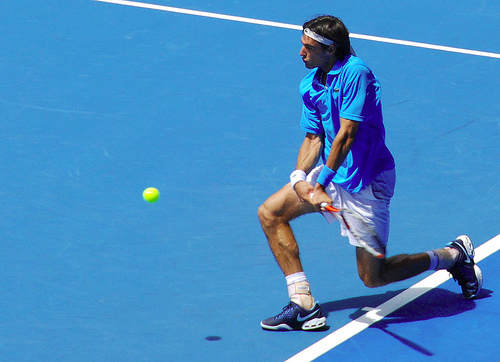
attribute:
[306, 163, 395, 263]
shorts — white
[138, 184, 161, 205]
ball — green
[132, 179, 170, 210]
ball — lime green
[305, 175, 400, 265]
tennis racket — yellow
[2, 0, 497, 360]
floor — blue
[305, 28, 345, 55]
band — white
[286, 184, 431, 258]
racket — red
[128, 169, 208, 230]
ball — green